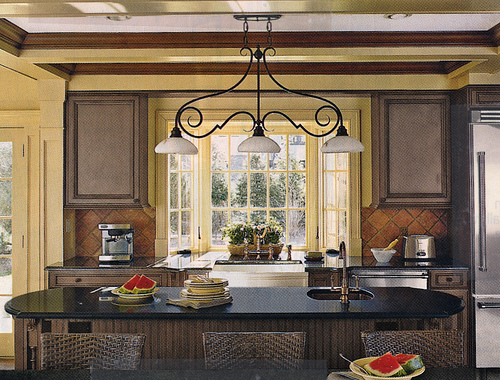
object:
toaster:
[399, 234, 437, 268]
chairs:
[356, 329, 467, 374]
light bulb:
[335, 136, 350, 153]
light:
[320, 136, 365, 154]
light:
[237, 135, 281, 156]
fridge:
[459, 110, 500, 373]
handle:
[478, 151, 489, 272]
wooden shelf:
[63, 89, 148, 211]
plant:
[220, 221, 247, 244]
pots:
[269, 242, 284, 255]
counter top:
[4, 287, 464, 319]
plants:
[267, 229, 280, 242]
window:
[161, 117, 354, 259]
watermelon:
[395, 352, 425, 372]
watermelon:
[363, 351, 407, 377]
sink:
[304, 287, 375, 302]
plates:
[184, 277, 227, 285]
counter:
[4, 280, 467, 363]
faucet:
[337, 240, 350, 304]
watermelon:
[131, 274, 157, 294]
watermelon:
[118, 273, 139, 293]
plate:
[111, 287, 157, 299]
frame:
[201, 125, 314, 251]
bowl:
[346, 355, 425, 380]